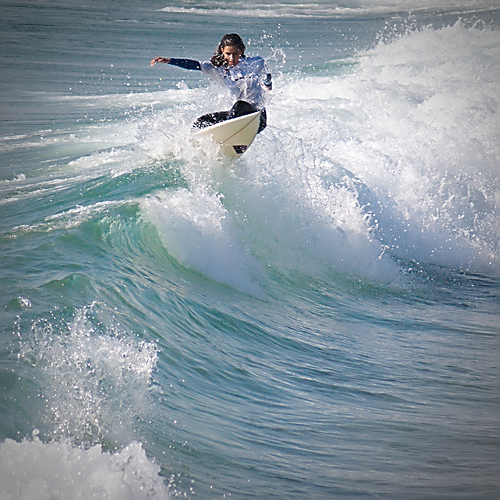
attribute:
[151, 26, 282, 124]
person — surfing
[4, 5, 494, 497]
water — white, blue, choppy, clear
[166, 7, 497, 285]
wave — large, white, curl, splashing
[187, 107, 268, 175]
surfboard — white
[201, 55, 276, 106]
shirt — white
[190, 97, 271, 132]
pants — blue, black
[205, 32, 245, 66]
hair — brown, blonde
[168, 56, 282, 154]
wetsuit — black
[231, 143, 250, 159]
symbol — black